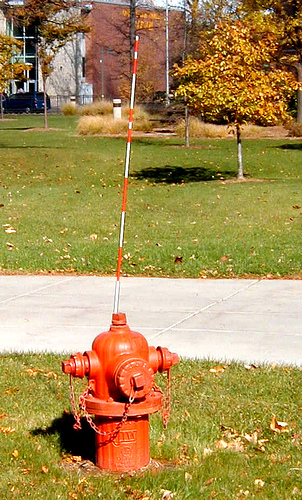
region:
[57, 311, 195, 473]
red fire hydrant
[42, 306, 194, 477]
fire hydrant in grass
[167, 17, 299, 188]
tree with yellow and red leaves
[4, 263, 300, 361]
cement sidewalk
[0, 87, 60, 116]
dark blue mini-van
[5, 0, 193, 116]
building with white and brown exterior walls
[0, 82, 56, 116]
minivan parked in a lot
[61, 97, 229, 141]
small brown shrubs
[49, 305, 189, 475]
red hyrdrant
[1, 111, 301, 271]
field of green grass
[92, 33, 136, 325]
The gray and orange pole.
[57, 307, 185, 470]
The hydrant in the grass area.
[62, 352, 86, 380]
The cap on the left.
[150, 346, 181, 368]
The cap on the right.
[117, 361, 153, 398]
The cap in the front.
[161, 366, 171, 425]
The chain on the right cap.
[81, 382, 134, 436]
The chain on the front cap.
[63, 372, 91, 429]
The chain on the left cap.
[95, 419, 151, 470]
The base of the hydrant.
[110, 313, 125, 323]
The top screw on the hydrant.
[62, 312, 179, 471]
the fire hydrant is red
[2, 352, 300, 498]
the leaves are on the grass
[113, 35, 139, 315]
the pole is silver and red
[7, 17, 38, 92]
the door has a metal frame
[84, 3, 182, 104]
the building is brown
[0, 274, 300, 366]
the side walk is made of cement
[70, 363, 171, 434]
the fire hydrant has chains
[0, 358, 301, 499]
the leaves are brown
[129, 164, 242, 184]
the tree casts a shadow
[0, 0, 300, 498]
the scene takes place outdoors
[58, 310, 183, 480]
a red fire hydrant by a sidewalk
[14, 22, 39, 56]
the windows of a building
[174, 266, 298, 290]
the edge of a sidewalk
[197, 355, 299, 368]
the edge of a sidewalk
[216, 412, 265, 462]
dry leaves on the ground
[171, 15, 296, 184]
a tree on a lawn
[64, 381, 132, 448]
the chains on a fire hydrant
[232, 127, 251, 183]
a trunk of a tree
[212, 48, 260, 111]
the leaves on a tree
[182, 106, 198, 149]
a trunk of a tree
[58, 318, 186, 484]
FIRE HYDRANT IS IN THE GRASSY AREA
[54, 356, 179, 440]
FIRE HYDRANT HAS CHAINS ON IT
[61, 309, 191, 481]
FIRE HYDRANT IS RED IN COLOR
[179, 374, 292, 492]
GRASSY AREA IS GREEN IN COLOR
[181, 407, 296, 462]
A COUPLE OF LEAVES ARE IN THE GRASSY AREA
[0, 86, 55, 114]
BLUE MINI VAN IS IN BACKGROUND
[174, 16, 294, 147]
FOLIAGE ON TREE IS YELLOW, ORANGE AND RED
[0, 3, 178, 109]
BRICK BUILDING IS IN THE BACKGROUND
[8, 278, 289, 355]
SIDEWALK IS BETWEEN THE GRASSY AREAS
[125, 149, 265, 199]
SHADOW ON GROUND IS DUE TO SUN